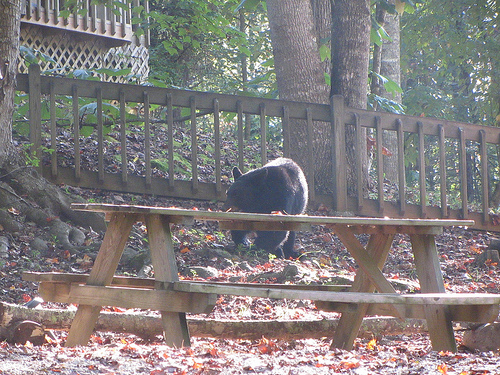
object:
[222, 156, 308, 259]
bear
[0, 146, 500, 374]
park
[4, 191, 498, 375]
leaves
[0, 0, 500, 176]
leaves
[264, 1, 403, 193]
tree trunk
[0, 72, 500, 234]
fence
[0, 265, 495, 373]
ground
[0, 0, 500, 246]
trees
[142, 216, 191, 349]
post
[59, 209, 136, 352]
post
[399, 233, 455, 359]
post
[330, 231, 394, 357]
post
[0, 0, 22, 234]
tree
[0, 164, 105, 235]
roots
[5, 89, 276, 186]
plants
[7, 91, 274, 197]
hill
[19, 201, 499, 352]
picnic table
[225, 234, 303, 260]
feet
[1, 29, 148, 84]
lattice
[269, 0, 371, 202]
tree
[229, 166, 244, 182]
ear